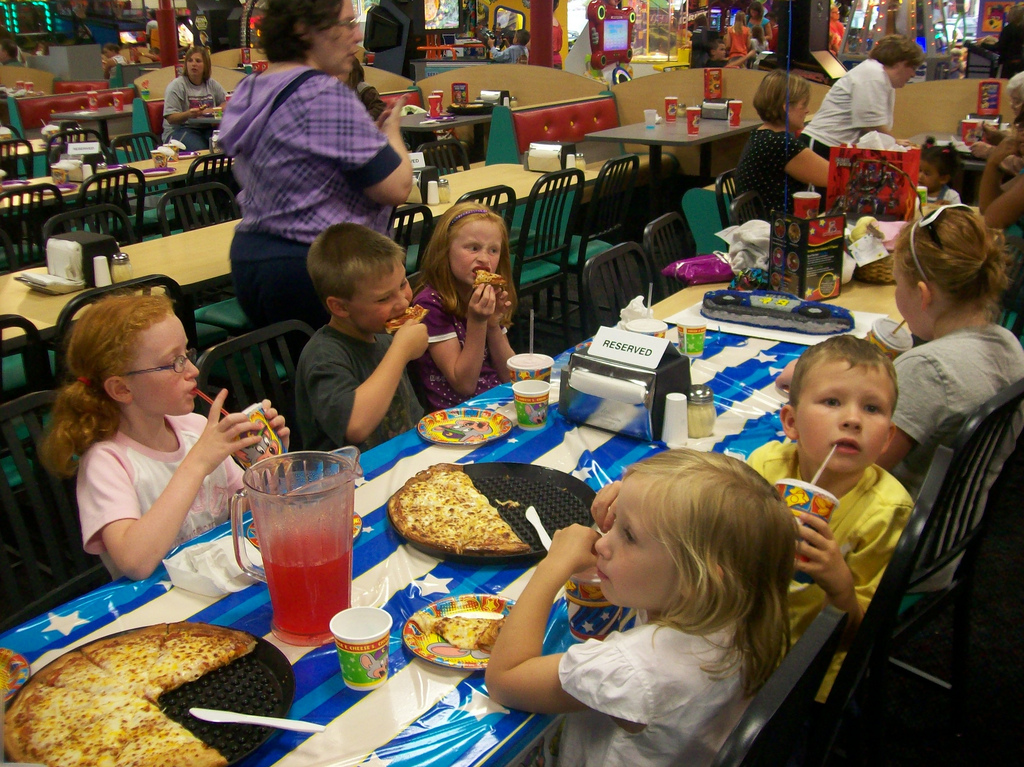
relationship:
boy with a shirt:
[285, 219, 435, 444] [287, 323, 439, 451]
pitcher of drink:
[231, 437, 361, 656] [259, 525, 353, 653]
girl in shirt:
[488, 439, 810, 762] [549, 625, 753, 762]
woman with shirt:
[207, 1, 432, 380] [209, 65, 402, 243]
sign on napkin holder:
[581, 318, 674, 373] [562, 350, 690, 446]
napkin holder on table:
[560, 336, 692, 442] [2, 208, 962, 762]